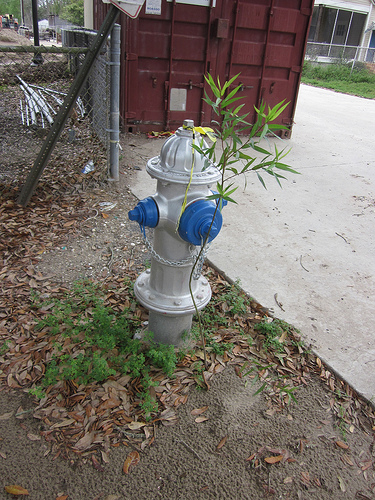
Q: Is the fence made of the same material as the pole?
A: Yes, both the fence and the pole are made of metal.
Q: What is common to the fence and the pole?
A: The material, both the fence and the pole are metallic.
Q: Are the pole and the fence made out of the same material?
A: Yes, both the pole and the fence are made of metal.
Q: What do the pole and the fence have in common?
A: The material, both the pole and the fence are metallic.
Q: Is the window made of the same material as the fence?
A: No, the window is made of glass and the fence is made of metal.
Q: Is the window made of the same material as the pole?
A: No, the window is made of glass and the pole is made of metal.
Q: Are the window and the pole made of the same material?
A: No, the window is made of glass and the pole is made of metal.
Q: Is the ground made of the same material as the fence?
A: No, the ground is made of concrete and the fence is made of metal.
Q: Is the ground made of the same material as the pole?
A: No, the ground is made of cement and the pole is made of metal.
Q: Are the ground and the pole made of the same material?
A: No, the ground is made of cement and the pole is made of metal.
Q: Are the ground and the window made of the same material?
A: No, the ground is made of cement and the window is made of glass.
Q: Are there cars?
A: No, there are no cars.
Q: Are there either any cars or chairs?
A: No, there are no cars or chairs.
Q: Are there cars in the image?
A: No, there are no cars.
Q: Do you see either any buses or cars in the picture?
A: No, there are no cars or buses.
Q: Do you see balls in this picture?
A: No, there are no balls.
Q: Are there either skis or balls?
A: No, there are no balls or skis.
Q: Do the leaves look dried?
A: Yes, the leaves are dried.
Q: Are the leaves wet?
A: No, the leaves are dried.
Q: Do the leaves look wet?
A: No, the leaves are dried.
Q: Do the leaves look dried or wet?
A: The leaves are dried.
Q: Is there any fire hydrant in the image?
A: Yes, there is a fire hydrant.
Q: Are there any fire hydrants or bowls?
A: Yes, there is a fire hydrant.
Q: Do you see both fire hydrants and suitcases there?
A: No, there is a fire hydrant but no suitcases.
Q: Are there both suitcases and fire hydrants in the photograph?
A: No, there is a fire hydrant but no suitcases.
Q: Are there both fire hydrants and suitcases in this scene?
A: No, there is a fire hydrant but no suitcases.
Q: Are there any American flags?
A: No, there are no American flags.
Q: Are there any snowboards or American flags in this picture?
A: No, there are no American flags or snowboards.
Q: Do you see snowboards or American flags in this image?
A: No, there are no American flags or snowboards.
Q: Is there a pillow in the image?
A: No, there are no pillows.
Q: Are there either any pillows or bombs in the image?
A: No, there are no pillows or bombs.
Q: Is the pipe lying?
A: Yes, the pipe is lying.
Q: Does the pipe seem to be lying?
A: Yes, the pipe is lying.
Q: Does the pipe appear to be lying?
A: Yes, the pipe is lying.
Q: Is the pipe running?
A: No, the pipe is lying.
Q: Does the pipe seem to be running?
A: No, the pipe is lying.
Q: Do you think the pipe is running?
A: No, the pipe is lying.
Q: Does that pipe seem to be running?
A: No, the pipe is lying.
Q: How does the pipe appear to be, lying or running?
A: The pipe is lying.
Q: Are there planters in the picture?
A: No, there are no planters.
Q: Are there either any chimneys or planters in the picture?
A: No, there are no planters or chimneys.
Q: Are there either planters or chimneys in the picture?
A: No, there are no planters or chimneys.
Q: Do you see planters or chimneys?
A: No, there are no planters or chimneys.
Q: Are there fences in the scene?
A: Yes, there is a fence.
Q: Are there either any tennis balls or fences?
A: Yes, there is a fence.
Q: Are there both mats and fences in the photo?
A: No, there is a fence but no mats.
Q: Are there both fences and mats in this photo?
A: No, there is a fence but no mats.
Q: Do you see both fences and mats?
A: No, there is a fence but no mats.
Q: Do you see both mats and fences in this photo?
A: No, there is a fence but no mats.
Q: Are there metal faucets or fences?
A: Yes, there is a metal fence.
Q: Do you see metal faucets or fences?
A: Yes, there is a metal fence.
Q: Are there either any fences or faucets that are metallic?
A: Yes, the fence is metallic.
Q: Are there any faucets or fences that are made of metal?
A: Yes, the fence is made of metal.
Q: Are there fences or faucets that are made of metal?
A: Yes, the fence is made of metal.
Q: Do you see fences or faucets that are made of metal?
A: Yes, the fence is made of metal.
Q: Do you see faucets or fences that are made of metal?
A: Yes, the fence is made of metal.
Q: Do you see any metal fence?
A: Yes, there is a metal fence.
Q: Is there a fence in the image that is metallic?
A: Yes, there is a fence that is metallic.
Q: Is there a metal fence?
A: Yes, there is a fence that is made of metal.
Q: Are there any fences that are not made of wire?
A: Yes, there is a fence that is made of metal.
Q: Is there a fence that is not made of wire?
A: Yes, there is a fence that is made of metal.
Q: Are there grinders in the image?
A: No, there are no grinders.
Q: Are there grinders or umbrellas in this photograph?
A: No, there are no grinders or umbrellas.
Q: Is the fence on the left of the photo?
A: Yes, the fence is on the left of the image.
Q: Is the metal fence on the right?
A: No, the fence is on the left of the image.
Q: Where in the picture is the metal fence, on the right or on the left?
A: The fence is on the left of the image.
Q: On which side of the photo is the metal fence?
A: The fence is on the left of the image.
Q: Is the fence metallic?
A: Yes, the fence is metallic.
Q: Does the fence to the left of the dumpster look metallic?
A: Yes, the fence is metallic.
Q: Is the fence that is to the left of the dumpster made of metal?
A: Yes, the fence is made of metal.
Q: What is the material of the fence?
A: The fence is made of metal.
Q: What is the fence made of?
A: The fence is made of metal.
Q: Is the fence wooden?
A: No, the fence is metallic.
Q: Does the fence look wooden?
A: No, the fence is metallic.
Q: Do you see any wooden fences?
A: No, there is a fence but it is metallic.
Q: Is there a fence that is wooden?
A: No, there is a fence but it is metallic.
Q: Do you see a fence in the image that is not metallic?
A: No, there is a fence but it is metallic.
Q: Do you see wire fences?
A: No, there is a fence but it is made of metal.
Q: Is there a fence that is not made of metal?
A: No, there is a fence but it is made of metal.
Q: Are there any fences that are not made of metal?
A: No, there is a fence but it is made of metal.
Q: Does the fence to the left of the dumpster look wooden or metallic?
A: The fence is metallic.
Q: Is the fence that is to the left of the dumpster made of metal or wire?
A: The fence is made of metal.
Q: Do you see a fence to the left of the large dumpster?
A: Yes, there is a fence to the left of the dumpster.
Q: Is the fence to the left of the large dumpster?
A: Yes, the fence is to the left of the dumpster.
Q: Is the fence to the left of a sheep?
A: No, the fence is to the left of the dumpster.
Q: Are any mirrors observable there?
A: No, there are no mirrors.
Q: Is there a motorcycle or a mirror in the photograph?
A: No, there are no mirrors or motorcycles.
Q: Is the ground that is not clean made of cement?
A: Yes, the ground is made of cement.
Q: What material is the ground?
A: The ground is made of concrete.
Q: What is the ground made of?
A: The ground is made of concrete.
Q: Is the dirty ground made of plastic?
A: No, the ground is made of concrete.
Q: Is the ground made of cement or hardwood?
A: The ground is made of cement.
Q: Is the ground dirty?
A: Yes, the ground is dirty.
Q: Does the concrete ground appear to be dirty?
A: Yes, the ground is dirty.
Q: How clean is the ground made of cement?
A: The ground is dirty.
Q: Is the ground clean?
A: No, the ground is dirty.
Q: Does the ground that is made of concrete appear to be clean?
A: No, the ground is dirty.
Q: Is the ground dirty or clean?
A: The ground is dirty.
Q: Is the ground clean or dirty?
A: The ground is dirty.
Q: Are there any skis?
A: No, there are no skis.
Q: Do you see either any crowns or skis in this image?
A: No, there are no skis or crowns.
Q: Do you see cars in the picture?
A: No, there are no cars.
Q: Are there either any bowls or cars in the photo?
A: No, there are no cars or bowls.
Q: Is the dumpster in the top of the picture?
A: Yes, the dumpster is in the top of the image.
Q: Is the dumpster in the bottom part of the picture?
A: No, the dumpster is in the top of the image.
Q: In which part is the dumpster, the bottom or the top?
A: The dumpster is in the top of the image.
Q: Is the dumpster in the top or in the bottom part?
A: The dumpster is in the top of the image.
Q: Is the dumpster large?
A: Yes, the dumpster is large.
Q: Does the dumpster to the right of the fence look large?
A: Yes, the dumpster is large.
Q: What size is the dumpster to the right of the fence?
A: The dumpster is large.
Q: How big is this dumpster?
A: The dumpster is large.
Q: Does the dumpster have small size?
A: No, the dumpster is large.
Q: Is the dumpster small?
A: No, the dumpster is large.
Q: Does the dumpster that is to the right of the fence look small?
A: No, the dumpster is large.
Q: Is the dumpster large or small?
A: The dumpster is large.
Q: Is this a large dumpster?
A: Yes, this is a large dumpster.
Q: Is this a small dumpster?
A: No, this is a large dumpster.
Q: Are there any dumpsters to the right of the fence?
A: Yes, there is a dumpster to the right of the fence.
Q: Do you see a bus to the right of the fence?
A: No, there is a dumpster to the right of the fence.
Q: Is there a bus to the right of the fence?
A: No, there is a dumpster to the right of the fence.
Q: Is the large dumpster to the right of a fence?
A: Yes, the dumpster is to the right of a fence.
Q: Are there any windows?
A: Yes, there is a window.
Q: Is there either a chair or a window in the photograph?
A: Yes, there is a window.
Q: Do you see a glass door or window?
A: Yes, there is a glass window.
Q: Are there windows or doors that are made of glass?
A: Yes, the window is made of glass.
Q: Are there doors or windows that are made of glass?
A: Yes, the window is made of glass.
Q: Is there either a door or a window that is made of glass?
A: Yes, the window is made of glass.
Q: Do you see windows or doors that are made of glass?
A: Yes, the window is made of glass.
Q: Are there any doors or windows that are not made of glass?
A: No, there is a window but it is made of glass.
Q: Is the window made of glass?
A: Yes, the window is made of glass.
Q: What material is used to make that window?
A: The window is made of glass.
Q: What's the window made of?
A: The window is made of glass.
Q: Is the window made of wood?
A: No, the window is made of glass.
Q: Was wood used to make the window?
A: No, the window is made of glass.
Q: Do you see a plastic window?
A: No, there is a window but it is made of glass.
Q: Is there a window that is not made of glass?
A: No, there is a window but it is made of glass.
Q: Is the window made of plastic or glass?
A: The window is made of glass.